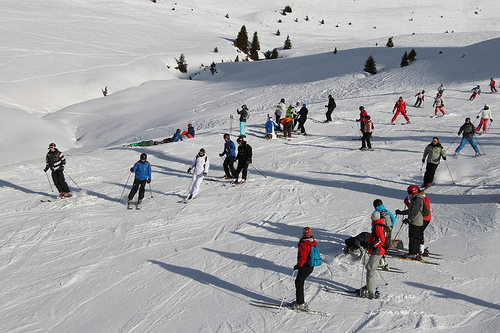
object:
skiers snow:
[387, 76, 498, 129]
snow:
[0, 210, 279, 333]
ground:
[3, 142, 500, 331]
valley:
[10, 80, 148, 144]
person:
[422, 137, 448, 187]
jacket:
[132, 160, 152, 181]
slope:
[0, 71, 497, 331]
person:
[43, 142, 73, 197]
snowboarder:
[396, 253, 440, 267]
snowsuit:
[43, 148, 66, 172]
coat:
[45, 148, 66, 172]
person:
[391, 96, 410, 124]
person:
[453, 117, 481, 157]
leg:
[455, 141, 467, 153]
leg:
[469, 139, 480, 153]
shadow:
[145, 260, 291, 308]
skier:
[396, 186, 431, 260]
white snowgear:
[183, 154, 209, 196]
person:
[358, 212, 391, 298]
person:
[187, 148, 210, 199]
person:
[475, 104, 494, 133]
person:
[359, 115, 375, 151]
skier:
[219, 132, 237, 179]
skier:
[237, 104, 250, 138]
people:
[288, 227, 319, 310]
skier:
[234, 137, 253, 182]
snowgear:
[231, 144, 252, 179]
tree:
[234, 24, 249, 54]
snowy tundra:
[205, 60, 319, 95]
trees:
[283, 35, 295, 50]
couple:
[162, 123, 195, 142]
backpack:
[307, 245, 322, 267]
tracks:
[0, 199, 284, 333]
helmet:
[407, 185, 418, 195]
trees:
[252, 31, 261, 51]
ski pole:
[119, 172, 133, 202]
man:
[128, 153, 151, 204]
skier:
[370, 199, 395, 267]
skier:
[418, 190, 431, 252]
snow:
[0, 6, 165, 67]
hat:
[437, 93, 441, 96]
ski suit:
[391, 100, 409, 122]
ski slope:
[4, 2, 498, 330]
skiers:
[413, 90, 425, 107]